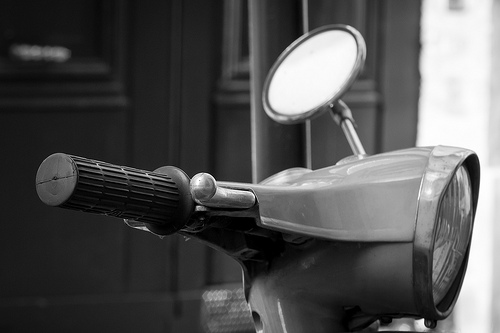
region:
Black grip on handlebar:
[13, 126, 212, 235]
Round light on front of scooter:
[378, 120, 485, 318]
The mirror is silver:
[249, 14, 390, 146]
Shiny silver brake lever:
[173, 152, 278, 217]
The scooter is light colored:
[144, 100, 461, 314]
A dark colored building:
[20, 14, 488, 283]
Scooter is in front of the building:
[21, 25, 471, 272]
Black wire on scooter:
[308, 296, 393, 329]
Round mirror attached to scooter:
[251, 22, 376, 156]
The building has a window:
[214, 15, 408, 99]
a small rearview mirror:
[192, 14, 462, 231]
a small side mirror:
[239, 10, 460, 258]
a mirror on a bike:
[48, 14, 426, 325]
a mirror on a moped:
[80, 22, 475, 332]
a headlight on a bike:
[203, 85, 498, 281]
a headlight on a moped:
[182, 77, 499, 319]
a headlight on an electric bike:
[97, 50, 499, 305]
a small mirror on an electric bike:
[229, 0, 409, 228]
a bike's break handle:
[171, 152, 294, 256]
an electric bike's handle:
[47, 113, 294, 269]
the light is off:
[408, 122, 482, 324]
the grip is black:
[30, 142, 199, 245]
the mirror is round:
[255, 17, 370, 131]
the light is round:
[415, 127, 485, 316]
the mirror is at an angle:
[260, 15, 389, 156]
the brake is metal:
[189, 162, 258, 215]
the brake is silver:
[185, 170, 265, 216]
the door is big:
[14, 3, 238, 137]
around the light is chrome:
[418, 160, 441, 199]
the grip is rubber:
[22, 132, 193, 236]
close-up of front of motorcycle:
[35, 23, 489, 331]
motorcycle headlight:
[407, 142, 482, 330]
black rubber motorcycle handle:
[36, 145, 194, 239]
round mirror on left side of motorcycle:
[257, 15, 379, 160]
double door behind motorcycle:
[6, 0, 418, 322]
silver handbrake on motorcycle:
[188, 171, 261, 213]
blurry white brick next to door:
[416, 0, 496, 328]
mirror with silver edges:
[256, 19, 375, 156]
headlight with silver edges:
[406, 140, 484, 329]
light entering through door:
[13, 39, 82, 62]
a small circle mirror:
[197, 6, 407, 206]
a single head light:
[276, 107, 498, 292]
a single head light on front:
[124, 70, 479, 327]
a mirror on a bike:
[192, 3, 415, 226]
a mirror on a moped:
[248, 7, 429, 201]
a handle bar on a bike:
[24, 129, 366, 309]